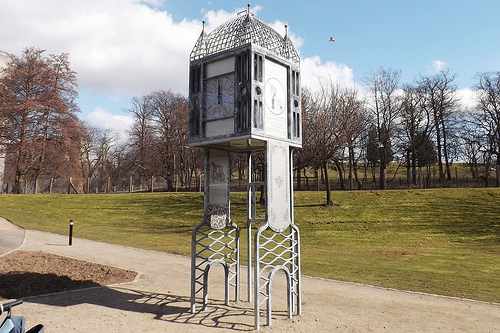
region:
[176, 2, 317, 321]
an old floor clock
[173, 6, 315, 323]
s silver stand of clock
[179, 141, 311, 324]
legs of clock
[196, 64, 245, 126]
a white clock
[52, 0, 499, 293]
a field cover with green grass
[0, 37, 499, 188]
trees behind a field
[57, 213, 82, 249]
a shot pole color black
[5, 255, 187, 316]
shadow cast on ground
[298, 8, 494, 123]
a bird flies over tress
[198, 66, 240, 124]
hour and minute handle of clock are on 12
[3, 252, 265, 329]
shadow of the clock tower on the ground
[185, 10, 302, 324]
small clock tower in the park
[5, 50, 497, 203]
dead trees lining the park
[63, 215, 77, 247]
black pole in the concrete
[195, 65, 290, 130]
faces of the clock on the tower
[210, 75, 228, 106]
black hands on a clock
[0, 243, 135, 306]
patch of dirt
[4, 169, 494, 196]
fence by the trees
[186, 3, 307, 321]
metal structure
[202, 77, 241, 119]
square clock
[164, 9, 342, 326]
grey and white clock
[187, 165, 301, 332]
clock has grey metal base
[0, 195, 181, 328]
light tan concrete near clock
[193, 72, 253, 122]
clock has white face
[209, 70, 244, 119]
black hands on clock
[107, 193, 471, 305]
green manicured lawn behind clock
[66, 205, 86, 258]
black marker on concrete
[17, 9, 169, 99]
white puffy clouds in sky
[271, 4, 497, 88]
sky is blue and white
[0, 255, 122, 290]
light brown dirt near concrete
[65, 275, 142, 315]
A shadow in the dirt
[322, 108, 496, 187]
Back trees in the field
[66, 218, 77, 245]
A black pole in the ground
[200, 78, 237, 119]
A clock on a small tower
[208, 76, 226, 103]
The hands of the clock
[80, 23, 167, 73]
Clouds above the field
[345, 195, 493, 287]
A field with some trees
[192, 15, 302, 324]
A small tower in the dirt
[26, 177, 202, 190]
A fence near the trees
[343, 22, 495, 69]
Blue sky above the trees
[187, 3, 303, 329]
A clock tower sculpture.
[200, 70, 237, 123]
A clock face on the tower.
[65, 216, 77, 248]
A black pole on the path.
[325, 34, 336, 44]
A bird in the sky.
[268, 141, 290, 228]
Ornate design on the side of the tower.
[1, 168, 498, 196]
A fence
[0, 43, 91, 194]
A tall reddish brown tree.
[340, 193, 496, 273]
Trimmed green lawn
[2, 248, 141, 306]
Unplanted flower bed.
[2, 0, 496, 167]
Fluffy white clouds in a blue sky.